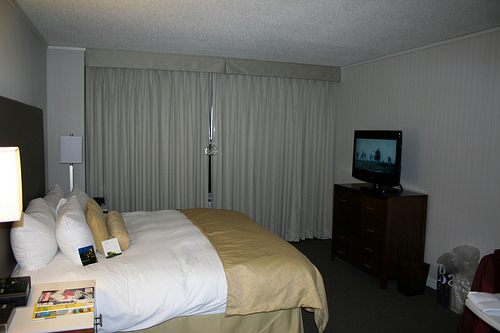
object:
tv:
[347, 130, 404, 184]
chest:
[333, 182, 426, 291]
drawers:
[359, 194, 388, 212]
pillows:
[52, 195, 98, 264]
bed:
[17, 206, 319, 333]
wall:
[338, 32, 499, 284]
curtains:
[212, 57, 337, 243]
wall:
[46, 51, 87, 205]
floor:
[290, 241, 467, 333]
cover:
[180, 206, 329, 329]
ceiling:
[20, 6, 499, 66]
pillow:
[7, 196, 58, 269]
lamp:
[59, 134, 82, 165]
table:
[93, 197, 104, 206]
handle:
[95, 312, 104, 332]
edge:
[48, 45, 87, 51]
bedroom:
[1, 2, 500, 330]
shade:
[60, 112, 76, 124]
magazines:
[34, 286, 96, 315]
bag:
[435, 251, 456, 304]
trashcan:
[397, 258, 431, 295]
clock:
[1, 277, 29, 305]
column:
[69, 164, 75, 192]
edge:
[395, 129, 403, 187]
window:
[84, 57, 343, 236]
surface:
[14, 312, 96, 332]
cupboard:
[0, 279, 98, 333]